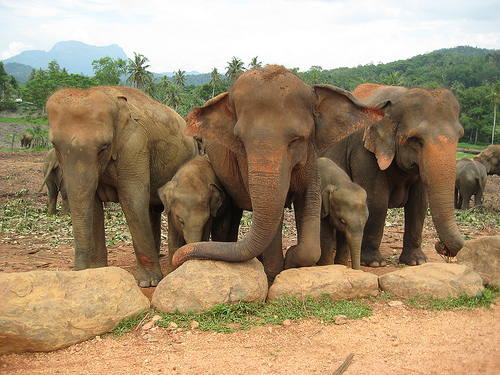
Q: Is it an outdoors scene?
A: Yes, it is outdoors.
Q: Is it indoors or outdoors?
A: It is outdoors.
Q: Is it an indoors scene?
A: No, it is outdoors.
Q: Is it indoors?
A: No, it is outdoors.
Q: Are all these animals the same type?
A: Yes, all the animals are elephants.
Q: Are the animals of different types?
A: No, all the animals are elephants.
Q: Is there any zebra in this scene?
A: No, there are no zebras.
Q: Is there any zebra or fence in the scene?
A: No, there are no zebras or fences.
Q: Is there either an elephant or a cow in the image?
A: Yes, there is an elephant.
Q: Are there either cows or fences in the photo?
A: No, there are no fences or cows.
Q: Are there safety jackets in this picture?
A: No, there are no safety jackets.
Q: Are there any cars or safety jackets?
A: No, there are no safety jackets or cars.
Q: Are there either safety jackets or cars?
A: No, there are no safety jackets or cars.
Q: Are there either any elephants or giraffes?
A: Yes, there are elephants.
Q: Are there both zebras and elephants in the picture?
A: No, there are elephants but no zebras.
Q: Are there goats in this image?
A: No, there are no goats.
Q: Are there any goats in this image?
A: No, there are no goats.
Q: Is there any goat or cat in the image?
A: No, there are no goats or cats.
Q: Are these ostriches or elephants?
A: These are elephants.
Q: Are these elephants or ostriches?
A: These are elephants.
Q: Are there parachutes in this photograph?
A: No, there are no parachutes.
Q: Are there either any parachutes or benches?
A: No, there are no parachutes or benches.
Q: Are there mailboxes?
A: No, there are no mailboxes.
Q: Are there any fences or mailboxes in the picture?
A: No, there are no mailboxes or fences.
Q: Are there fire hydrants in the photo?
A: No, there are no fire hydrants.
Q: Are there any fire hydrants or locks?
A: No, there are no fire hydrants or locks.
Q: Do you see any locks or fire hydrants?
A: No, there are no fire hydrants or locks.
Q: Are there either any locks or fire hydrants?
A: No, there are no fire hydrants or locks.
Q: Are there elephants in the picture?
A: Yes, there is an elephant.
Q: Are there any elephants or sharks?
A: Yes, there is an elephant.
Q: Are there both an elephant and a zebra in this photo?
A: No, there is an elephant but no zebras.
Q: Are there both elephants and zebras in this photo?
A: No, there is an elephant but no zebras.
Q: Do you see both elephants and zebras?
A: No, there is an elephant but no zebras.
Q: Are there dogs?
A: No, there are no dogs.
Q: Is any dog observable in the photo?
A: No, there are no dogs.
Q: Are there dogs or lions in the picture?
A: No, there are no dogs or lions.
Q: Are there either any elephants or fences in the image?
A: Yes, there is an elephant.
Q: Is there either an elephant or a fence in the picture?
A: Yes, there is an elephant.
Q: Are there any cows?
A: No, there are no cows.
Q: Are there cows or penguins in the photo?
A: No, there are no cows or penguins.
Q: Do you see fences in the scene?
A: No, there are no fences.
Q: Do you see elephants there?
A: Yes, there is an elephant.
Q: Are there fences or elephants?
A: Yes, there is an elephant.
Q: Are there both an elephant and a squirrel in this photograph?
A: No, there is an elephant but no squirrels.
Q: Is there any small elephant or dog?
A: Yes, there is a small elephant.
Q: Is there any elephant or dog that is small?
A: Yes, the elephant is small.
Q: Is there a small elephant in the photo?
A: Yes, there is a small elephant.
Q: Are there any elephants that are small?
A: Yes, there is an elephant that is small.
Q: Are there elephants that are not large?
A: Yes, there is a small elephant.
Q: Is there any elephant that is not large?
A: Yes, there is a small elephant.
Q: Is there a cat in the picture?
A: No, there are no cats.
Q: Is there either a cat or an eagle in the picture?
A: No, there are no cats or eagles.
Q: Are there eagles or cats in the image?
A: No, there are no cats or eagles.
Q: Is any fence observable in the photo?
A: No, there are no fences.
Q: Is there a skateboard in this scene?
A: No, there are no skateboards.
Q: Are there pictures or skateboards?
A: No, there are no skateboards or pictures.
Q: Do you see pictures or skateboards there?
A: No, there are no skateboards or pictures.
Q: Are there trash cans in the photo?
A: No, there are no trash cans.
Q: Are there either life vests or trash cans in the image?
A: No, there are no trash cans or life vests.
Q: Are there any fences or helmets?
A: No, there are no fences or helmets.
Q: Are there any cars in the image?
A: No, there are no cars.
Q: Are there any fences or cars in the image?
A: No, there are no cars or fences.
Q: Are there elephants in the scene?
A: Yes, there is an elephant.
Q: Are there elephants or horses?
A: Yes, there is an elephant.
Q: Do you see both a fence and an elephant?
A: No, there is an elephant but no fences.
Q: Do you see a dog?
A: No, there are no dogs.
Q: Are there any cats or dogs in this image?
A: No, there are no dogs or cats.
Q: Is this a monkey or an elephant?
A: This is an elephant.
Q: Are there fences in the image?
A: No, there are no fences.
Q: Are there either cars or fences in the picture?
A: No, there are no fences or cars.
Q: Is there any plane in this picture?
A: No, there are no airplanes.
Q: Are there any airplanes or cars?
A: No, there are no airplanes or cars.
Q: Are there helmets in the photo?
A: No, there are no helmets.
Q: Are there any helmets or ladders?
A: No, there are no helmets or ladders.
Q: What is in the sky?
A: The clouds are in the sky.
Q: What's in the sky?
A: The clouds are in the sky.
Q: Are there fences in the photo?
A: No, there are no fences.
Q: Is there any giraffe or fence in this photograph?
A: No, there are no fences or giraffes.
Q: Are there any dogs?
A: No, there are no dogs.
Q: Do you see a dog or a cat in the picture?
A: No, there are no dogs or cats.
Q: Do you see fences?
A: No, there are no fences.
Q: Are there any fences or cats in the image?
A: No, there are no fences or cats.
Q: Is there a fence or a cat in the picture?
A: No, there are no fences or cats.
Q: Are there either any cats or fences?
A: No, there are no fences or cats.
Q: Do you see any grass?
A: Yes, there is grass.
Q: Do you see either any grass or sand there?
A: Yes, there is grass.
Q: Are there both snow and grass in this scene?
A: No, there is grass but no snow.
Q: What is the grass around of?
A: The grass is around the rocks.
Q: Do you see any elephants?
A: Yes, there is an elephant.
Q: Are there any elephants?
A: Yes, there is an elephant.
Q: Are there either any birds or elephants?
A: Yes, there is an elephant.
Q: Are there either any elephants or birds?
A: Yes, there is an elephant.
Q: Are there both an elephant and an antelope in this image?
A: No, there is an elephant but no antelopes.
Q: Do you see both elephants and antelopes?
A: No, there is an elephant but no antelopes.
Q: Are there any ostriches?
A: No, there are no ostriches.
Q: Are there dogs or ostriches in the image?
A: No, there are no ostriches or dogs.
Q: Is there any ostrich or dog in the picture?
A: No, there are no ostriches or dogs.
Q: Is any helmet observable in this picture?
A: No, there are no helmets.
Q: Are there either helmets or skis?
A: No, there are no helmets or skis.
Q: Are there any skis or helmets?
A: No, there are no helmets or skis.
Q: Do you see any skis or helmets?
A: No, there are no helmets or skis.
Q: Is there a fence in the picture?
A: No, there are no fences.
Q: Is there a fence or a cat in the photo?
A: No, there are no fences or cats.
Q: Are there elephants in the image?
A: Yes, there are elephants.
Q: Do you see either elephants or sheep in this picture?
A: Yes, there are elephants.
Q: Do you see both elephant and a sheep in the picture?
A: No, there are elephants but no sheep.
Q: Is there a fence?
A: No, there are no fences.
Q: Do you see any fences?
A: No, there are no fences.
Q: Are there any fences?
A: No, there are no fences.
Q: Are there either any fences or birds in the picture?
A: No, there are no fences or birds.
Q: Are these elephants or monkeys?
A: These are elephants.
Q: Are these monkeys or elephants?
A: These are elephants.